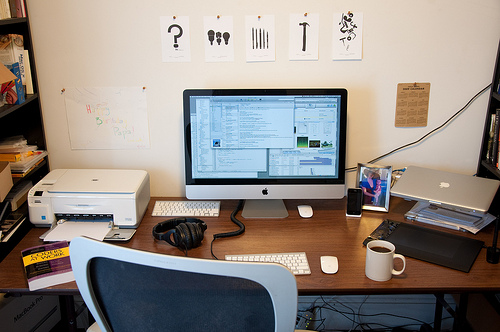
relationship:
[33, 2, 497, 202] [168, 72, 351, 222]
wall behind monitor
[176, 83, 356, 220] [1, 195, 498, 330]
computer monitor on desk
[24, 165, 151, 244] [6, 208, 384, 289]
printer on desk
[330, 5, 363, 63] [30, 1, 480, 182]
paper on wall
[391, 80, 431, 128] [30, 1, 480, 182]
paper on wall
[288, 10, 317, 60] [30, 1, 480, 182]
paper on wall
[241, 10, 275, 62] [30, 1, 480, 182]
paper on wall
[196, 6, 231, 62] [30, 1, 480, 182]
paper on wall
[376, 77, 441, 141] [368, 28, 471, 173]
calendar on wall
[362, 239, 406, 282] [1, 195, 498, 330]
cup on desk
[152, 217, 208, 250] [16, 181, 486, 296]
headphone on desk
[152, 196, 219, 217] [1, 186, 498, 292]
keyboard on desk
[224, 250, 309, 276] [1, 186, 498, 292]
keyboard on desk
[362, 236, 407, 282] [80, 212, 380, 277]
cup on desk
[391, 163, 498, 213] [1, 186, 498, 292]
laptop on desk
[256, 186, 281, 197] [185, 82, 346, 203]
logo on computer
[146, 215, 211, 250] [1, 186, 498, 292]
headphone on desk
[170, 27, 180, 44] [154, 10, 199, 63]
question mark on paper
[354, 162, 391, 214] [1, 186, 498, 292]
picture on desk